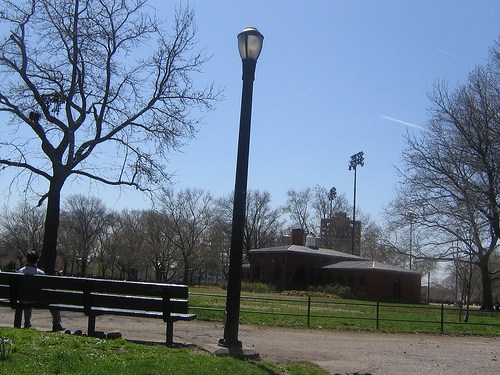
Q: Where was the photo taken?
A: It was taken at the park.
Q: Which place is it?
A: It is a park.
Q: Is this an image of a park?
A: Yes, it is showing a park.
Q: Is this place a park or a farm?
A: It is a park.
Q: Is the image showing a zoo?
A: No, the picture is showing a park.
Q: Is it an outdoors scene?
A: Yes, it is outdoors.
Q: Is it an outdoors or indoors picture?
A: It is outdoors.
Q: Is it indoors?
A: No, it is outdoors.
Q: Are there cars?
A: No, there are no cars.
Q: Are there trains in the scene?
A: No, there are no trains.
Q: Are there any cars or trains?
A: No, there are no trains or cars.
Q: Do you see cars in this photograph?
A: No, there are no cars.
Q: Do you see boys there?
A: No, there are no boys.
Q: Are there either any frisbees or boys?
A: No, there are no boys or frisbees.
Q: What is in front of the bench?
A: The tree is in front of the bench.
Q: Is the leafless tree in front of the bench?
A: Yes, the tree is in front of the bench.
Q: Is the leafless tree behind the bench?
A: No, the tree is in front of the bench.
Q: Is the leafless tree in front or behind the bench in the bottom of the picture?
A: The tree is in front of the bench.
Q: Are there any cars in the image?
A: No, there are no cars.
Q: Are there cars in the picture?
A: No, there are no cars.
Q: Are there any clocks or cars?
A: No, there are no cars or clocks.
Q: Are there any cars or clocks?
A: No, there are no cars or clocks.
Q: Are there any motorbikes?
A: No, there are no motorbikes.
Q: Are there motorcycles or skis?
A: No, there are no motorcycles or skis.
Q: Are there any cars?
A: No, there are no cars.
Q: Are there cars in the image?
A: No, there are no cars.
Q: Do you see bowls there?
A: No, there are no bowls.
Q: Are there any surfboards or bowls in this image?
A: No, there are no bowls or surfboards.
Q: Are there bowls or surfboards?
A: No, there are no bowls or surfboards.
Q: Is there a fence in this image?
A: Yes, there is a fence.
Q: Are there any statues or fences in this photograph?
A: Yes, there is a fence.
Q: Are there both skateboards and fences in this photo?
A: No, there is a fence but no skateboards.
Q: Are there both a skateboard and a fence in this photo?
A: No, there is a fence but no skateboards.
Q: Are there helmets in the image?
A: No, there are no helmets.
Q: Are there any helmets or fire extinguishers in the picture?
A: No, there are no helmets or fire extinguishers.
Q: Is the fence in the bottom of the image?
A: Yes, the fence is in the bottom of the image.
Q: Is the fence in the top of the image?
A: No, the fence is in the bottom of the image.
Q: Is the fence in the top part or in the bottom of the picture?
A: The fence is in the bottom of the image.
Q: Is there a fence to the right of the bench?
A: Yes, there is a fence to the right of the bench.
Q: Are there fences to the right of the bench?
A: Yes, there is a fence to the right of the bench.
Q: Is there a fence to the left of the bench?
A: No, the fence is to the right of the bench.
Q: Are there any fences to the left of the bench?
A: No, the fence is to the right of the bench.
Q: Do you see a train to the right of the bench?
A: No, there is a fence to the right of the bench.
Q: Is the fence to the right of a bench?
A: Yes, the fence is to the right of a bench.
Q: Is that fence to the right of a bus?
A: No, the fence is to the right of a bench.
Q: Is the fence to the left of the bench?
A: No, the fence is to the right of the bench.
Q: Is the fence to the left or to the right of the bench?
A: The fence is to the right of the bench.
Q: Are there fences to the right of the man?
A: Yes, there is a fence to the right of the man.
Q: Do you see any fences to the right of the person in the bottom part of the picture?
A: Yes, there is a fence to the right of the man.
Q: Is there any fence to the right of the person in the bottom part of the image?
A: Yes, there is a fence to the right of the man.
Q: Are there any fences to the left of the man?
A: No, the fence is to the right of the man.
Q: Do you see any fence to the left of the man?
A: No, the fence is to the right of the man.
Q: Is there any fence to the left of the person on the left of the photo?
A: No, the fence is to the right of the man.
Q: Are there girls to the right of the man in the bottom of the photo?
A: No, there is a fence to the right of the man.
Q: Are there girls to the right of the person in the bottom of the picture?
A: No, there is a fence to the right of the man.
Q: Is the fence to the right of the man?
A: Yes, the fence is to the right of the man.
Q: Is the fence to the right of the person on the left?
A: Yes, the fence is to the right of the man.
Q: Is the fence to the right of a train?
A: No, the fence is to the right of the man.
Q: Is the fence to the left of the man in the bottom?
A: No, the fence is to the right of the man.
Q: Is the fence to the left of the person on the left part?
A: No, the fence is to the right of the man.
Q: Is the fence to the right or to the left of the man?
A: The fence is to the right of the man.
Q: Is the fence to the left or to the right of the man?
A: The fence is to the right of the man.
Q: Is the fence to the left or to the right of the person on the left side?
A: The fence is to the right of the man.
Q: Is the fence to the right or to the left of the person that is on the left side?
A: The fence is to the right of the man.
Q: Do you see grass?
A: Yes, there is grass.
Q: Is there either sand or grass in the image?
A: Yes, there is grass.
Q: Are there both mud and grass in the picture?
A: No, there is grass but no mud.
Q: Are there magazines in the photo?
A: No, there are no magazines.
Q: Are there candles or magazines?
A: No, there are no magazines or candles.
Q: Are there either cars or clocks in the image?
A: No, there are no cars or clocks.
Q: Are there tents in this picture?
A: No, there are no tents.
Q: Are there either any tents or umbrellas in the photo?
A: No, there are no tents or umbrellas.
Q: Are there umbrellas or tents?
A: No, there are no tents or umbrellas.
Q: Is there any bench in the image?
A: Yes, there is a bench.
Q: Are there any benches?
A: Yes, there is a bench.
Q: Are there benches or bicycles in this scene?
A: Yes, there is a bench.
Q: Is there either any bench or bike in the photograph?
A: Yes, there is a bench.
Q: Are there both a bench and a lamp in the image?
A: Yes, there are both a bench and a lamp.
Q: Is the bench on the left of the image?
A: Yes, the bench is on the left of the image.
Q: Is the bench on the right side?
A: No, the bench is on the left of the image.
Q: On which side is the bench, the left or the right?
A: The bench is on the left of the image.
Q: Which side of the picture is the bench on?
A: The bench is on the left of the image.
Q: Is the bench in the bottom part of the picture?
A: Yes, the bench is in the bottom of the image.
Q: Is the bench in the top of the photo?
A: No, the bench is in the bottom of the image.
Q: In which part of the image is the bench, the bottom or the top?
A: The bench is in the bottom of the image.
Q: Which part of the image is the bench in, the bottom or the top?
A: The bench is in the bottom of the image.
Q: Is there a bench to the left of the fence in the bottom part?
A: Yes, there is a bench to the left of the fence.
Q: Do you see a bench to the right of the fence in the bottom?
A: No, the bench is to the left of the fence.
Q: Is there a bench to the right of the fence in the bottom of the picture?
A: No, the bench is to the left of the fence.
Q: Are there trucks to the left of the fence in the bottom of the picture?
A: No, there is a bench to the left of the fence.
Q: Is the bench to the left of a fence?
A: Yes, the bench is to the left of a fence.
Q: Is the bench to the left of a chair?
A: No, the bench is to the left of a fence.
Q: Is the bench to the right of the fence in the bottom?
A: No, the bench is to the left of the fence.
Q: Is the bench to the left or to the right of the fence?
A: The bench is to the left of the fence.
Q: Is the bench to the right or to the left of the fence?
A: The bench is to the left of the fence.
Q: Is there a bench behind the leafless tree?
A: Yes, there is a bench behind the tree.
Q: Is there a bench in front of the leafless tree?
A: No, the bench is behind the tree.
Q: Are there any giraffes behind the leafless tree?
A: No, there is a bench behind the tree.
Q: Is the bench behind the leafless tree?
A: Yes, the bench is behind the tree.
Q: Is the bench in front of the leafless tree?
A: No, the bench is behind the tree.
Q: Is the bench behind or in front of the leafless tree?
A: The bench is behind the tree.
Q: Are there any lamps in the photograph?
A: Yes, there is a lamp.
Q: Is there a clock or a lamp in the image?
A: Yes, there is a lamp.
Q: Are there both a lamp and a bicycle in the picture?
A: No, there is a lamp but no bicycles.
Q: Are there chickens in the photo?
A: No, there are no chickens.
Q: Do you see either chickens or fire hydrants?
A: No, there are no chickens or fire hydrants.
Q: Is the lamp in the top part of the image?
A: Yes, the lamp is in the top of the image.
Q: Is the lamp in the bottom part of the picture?
A: No, the lamp is in the top of the image.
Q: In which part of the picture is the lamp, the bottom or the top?
A: The lamp is in the top of the image.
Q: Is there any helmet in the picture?
A: No, there are no helmets.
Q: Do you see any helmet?
A: No, there are no helmets.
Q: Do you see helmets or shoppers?
A: No, there are no helmets or shoppers.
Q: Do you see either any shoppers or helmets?
A: No, there are no helmets or shoppers.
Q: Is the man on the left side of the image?
A: Yes, the man is on the left of the image.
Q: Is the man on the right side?
A: No, the man is on the left of the image.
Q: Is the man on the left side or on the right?
A: The man is on the left of the image.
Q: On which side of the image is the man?
A: The man is on the left of the image.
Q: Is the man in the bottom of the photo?
A: Yes, the man is in the bottom of the image.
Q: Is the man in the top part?
A: No, the man is in the bottom of the image.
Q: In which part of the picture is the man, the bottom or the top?
A: The man is in the bottom of the image.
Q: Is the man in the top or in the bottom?
A: The man is in the bottom of the image.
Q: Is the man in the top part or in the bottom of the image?
A: The man is in the bottom of the image.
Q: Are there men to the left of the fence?
A: Yes, there is a man to the left of the fence.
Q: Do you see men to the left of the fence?
A: Yes, there is a man to the left of the fence.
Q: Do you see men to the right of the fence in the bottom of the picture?
A: No, the man is to the left of the fence.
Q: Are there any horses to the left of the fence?
A: No, there is a man to the left of the fence.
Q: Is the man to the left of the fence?
A: Yes, the man is to the left of the fence.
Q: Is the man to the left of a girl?
A: No, the man is to the left of the fence.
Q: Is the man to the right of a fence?
A: No, the man is to the left of a fence.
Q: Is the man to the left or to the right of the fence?
A: The man is to the left of the fence.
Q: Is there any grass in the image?
A: Yes, there is grass.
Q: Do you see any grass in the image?
A: Yes, there is grass.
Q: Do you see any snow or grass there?
A: Yes, there is grass.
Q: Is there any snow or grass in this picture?
A: Yes, there is grass.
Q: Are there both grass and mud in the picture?
A: No, there is grass but no mud.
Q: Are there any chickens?
A: No, there are no chickens.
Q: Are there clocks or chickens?
A: No, there are no chickens or clocks.